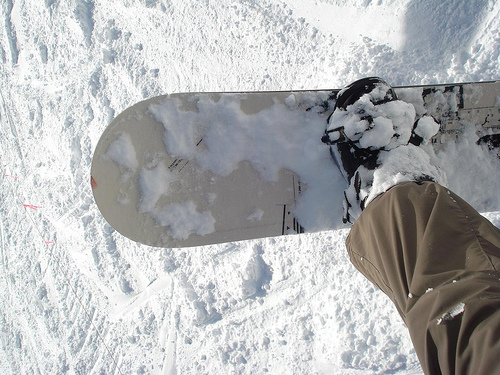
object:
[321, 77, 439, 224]
shoe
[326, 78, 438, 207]
snow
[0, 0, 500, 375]
ground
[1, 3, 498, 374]
snow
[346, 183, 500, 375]
wrinkles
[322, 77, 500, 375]
person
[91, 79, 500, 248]
board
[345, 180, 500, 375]
pant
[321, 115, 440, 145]
strap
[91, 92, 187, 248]
tip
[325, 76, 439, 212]
boot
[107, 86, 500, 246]
snow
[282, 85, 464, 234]
stripes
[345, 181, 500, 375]
leg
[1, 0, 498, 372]
hill side